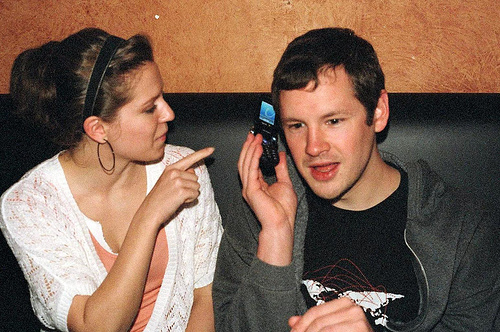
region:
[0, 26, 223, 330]
Women pointing at a man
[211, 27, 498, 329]
Man talking on a cellphone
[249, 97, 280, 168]
Black flip cellphone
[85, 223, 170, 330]
Peach shirt worn by a women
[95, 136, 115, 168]
Hoop earring hanging from a women's right ear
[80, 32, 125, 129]
Black headband worn by a women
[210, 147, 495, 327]
Grey jacket worn by a man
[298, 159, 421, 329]
Black T-shirt with red and white design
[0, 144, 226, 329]
Short sleeved white cardigan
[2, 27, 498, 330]
Women and a man sitting on a couch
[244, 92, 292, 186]
a black cellular phone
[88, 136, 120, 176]
a large hoop earing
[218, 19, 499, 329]
a man talks on his cell phone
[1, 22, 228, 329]
a woman points her finger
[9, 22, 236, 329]
a woman wears a black headband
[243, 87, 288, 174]
a small black phone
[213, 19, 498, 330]
a man wears a black shirt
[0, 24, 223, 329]
a woman with brown hair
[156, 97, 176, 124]
the nose of a woman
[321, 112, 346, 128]
a man's eye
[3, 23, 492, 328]
A woman pointing at a man on the phone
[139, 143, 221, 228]
A woman's hand pointing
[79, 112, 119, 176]
An ear with a large loop earring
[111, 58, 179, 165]
A woman's face in profile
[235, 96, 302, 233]
A hand with a mobile phone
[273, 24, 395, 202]
A man's head with his mouth open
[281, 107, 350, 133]
A man's eyes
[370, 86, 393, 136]
A man's left ear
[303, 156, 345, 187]
A man's mouth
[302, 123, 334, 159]
A man's nose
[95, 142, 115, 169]
An earring hanging down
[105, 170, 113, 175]
Shadow cast by the earring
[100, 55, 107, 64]
Band holding hair in place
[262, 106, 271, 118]
A cell phone screen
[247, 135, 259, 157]
fingers on a cellphone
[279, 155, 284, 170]
Thumb on the cellphone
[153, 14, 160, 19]
A white spot on the wall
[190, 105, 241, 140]
The couch against the wall